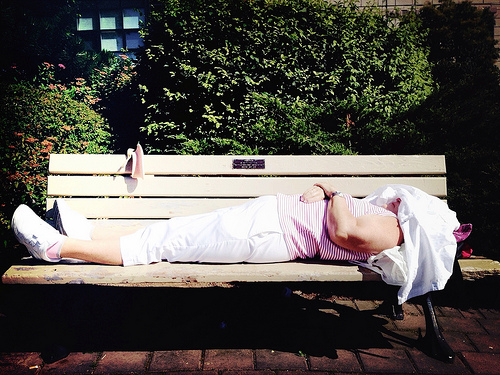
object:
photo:
[0, 0, 499, 374]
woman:
[8, 181, 476, 266]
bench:
[0, 150, 499, 363]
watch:
[325, 190, 347, 200]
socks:
[44, 239, 66, 260]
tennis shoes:
[8, 201, 62, 266]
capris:
[120, 194, 290, 267]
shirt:
[274, 187, 401, 263]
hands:
[297, 187, 327, 204]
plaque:
[231, 158, 269, 170]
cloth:
[360, 181, 462, 307]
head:
[380, 190, 471, 256]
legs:
[421, 293, 447, 339]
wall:
[342, 0, 499, 74]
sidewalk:
[0, 280, 499, 375]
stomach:
[290, 192, 340, 217]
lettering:
[232, 157, 264, 170]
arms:
[320, 194, 401, 255]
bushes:
[0, 0, 499, 256]